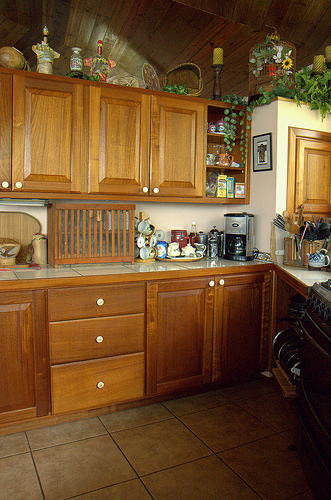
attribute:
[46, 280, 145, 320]
drawer — closed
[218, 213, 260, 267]
plane — white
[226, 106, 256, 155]
leaves — hanging down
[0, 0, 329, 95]
ceiling — wood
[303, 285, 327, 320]
knobs — black